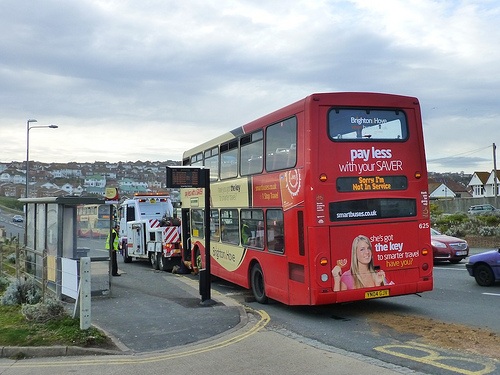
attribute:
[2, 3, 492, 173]
sky — cloudy, blue 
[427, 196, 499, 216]
fence — wooden, privacy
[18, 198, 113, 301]
bus stop — green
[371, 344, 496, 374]
letter b — yellow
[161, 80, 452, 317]
bus — red, double decker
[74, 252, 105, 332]
sign — white, black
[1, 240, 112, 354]
grass — green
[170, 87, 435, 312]
bus — red, painted, large, white, double-decker, double decker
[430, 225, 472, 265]
car — red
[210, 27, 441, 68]
sky — cloudy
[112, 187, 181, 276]
tow truck — white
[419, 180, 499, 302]
car — red, silver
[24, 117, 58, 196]
lamp post — metal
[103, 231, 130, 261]
vest — green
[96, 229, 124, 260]
vest — yellow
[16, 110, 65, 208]
lamp post — metal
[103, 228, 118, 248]
vest — yellow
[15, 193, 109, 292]
bus stop — glass